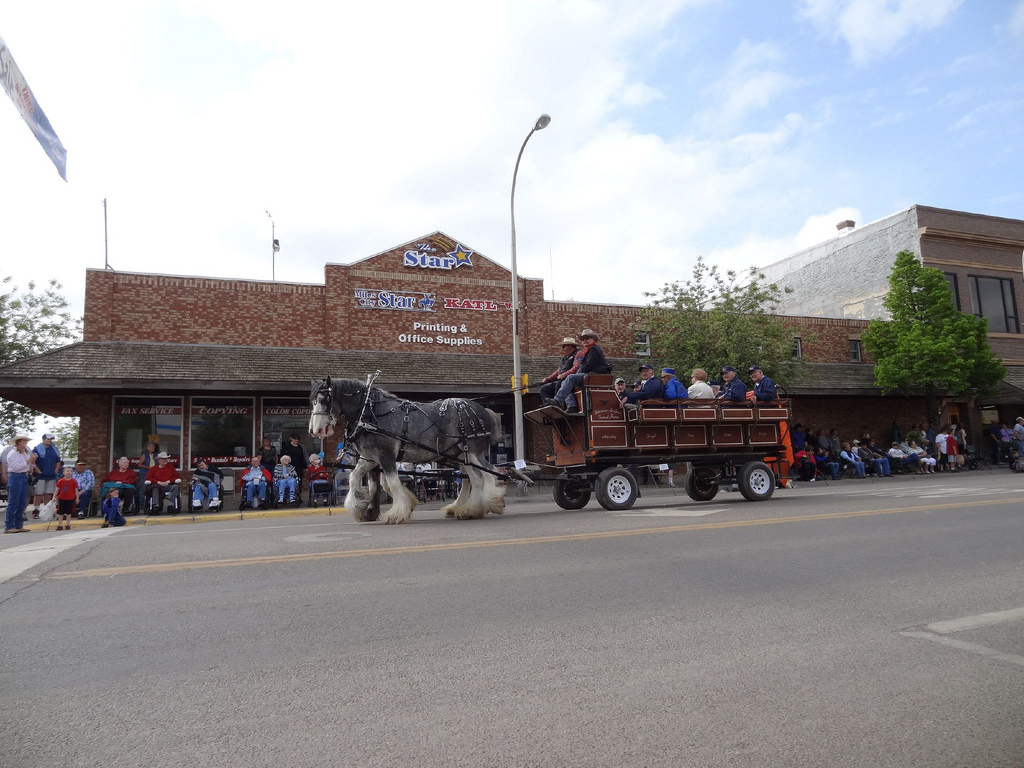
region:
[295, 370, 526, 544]
THIS IS A GREY AND WHITE HORSE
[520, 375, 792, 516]
THIS IS A WAGON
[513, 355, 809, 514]
THIS IS A BROWN WAGON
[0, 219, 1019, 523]
THIS BUILDING IS BRICK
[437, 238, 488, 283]
THIS IS A STAR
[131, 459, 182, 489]
THIS MAN IS WEARING A RED SHIRT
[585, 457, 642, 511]
THIS IS A WHEEL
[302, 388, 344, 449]
THIS HORSE HAS A WHITE FACE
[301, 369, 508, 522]
the horse is gray and white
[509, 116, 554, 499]
the street light is gray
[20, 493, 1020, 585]
the double lines are yellow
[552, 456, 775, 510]
the wheels are black with white rims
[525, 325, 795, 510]
the people on the trailer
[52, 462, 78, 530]
the child is standing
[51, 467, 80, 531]
the child wearing a red shirt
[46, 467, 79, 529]
the child wearing black shorts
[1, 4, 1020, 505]
the buildings under the blue sky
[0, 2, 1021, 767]
the clouds and the sky is above the gray road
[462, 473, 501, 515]
leg of the horse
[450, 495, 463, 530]
leg of the horse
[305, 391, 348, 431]
head of the horse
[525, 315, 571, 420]
person on the carriage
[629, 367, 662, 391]
person on the carriage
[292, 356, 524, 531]
two grey horses pulling a wagon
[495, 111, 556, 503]
lamp post on the side walk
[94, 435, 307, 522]
people sitting on the sidewalk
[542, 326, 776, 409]
people in the wagon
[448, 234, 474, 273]
star on the sign on the building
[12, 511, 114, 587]
white stripe painted across the street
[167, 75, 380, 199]
sky is obscured by clouds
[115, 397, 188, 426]
writing on the top of the window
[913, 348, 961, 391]
green leaves on the tree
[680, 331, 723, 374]
green leaves on the tree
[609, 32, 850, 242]
clouds in the sky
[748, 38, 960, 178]
blue sky above land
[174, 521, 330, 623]
yellow line on ground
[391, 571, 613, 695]
street next to the horse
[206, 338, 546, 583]
horses in front of carriage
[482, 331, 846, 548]
object with wheels on it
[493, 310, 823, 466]
people in the carriage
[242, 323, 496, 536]
horse pulling wagon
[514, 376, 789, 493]
wagon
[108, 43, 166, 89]
white clouds in blue sky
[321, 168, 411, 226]
white clouds in blue sky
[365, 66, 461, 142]
white clouds in blue sky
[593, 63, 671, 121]
white clouds in blue sky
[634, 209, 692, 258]
white clouds in blue sky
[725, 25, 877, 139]
white clouds in blue sky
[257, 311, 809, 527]
horse pulling wagon full of people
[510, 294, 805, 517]
people in a brown wagon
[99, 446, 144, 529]
person in red shirt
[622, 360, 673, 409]
person in blue shirt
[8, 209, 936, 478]
red brick building with star sign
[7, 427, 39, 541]
person wearing cowboy hat and white shirt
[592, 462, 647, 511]
white wheel with black tire